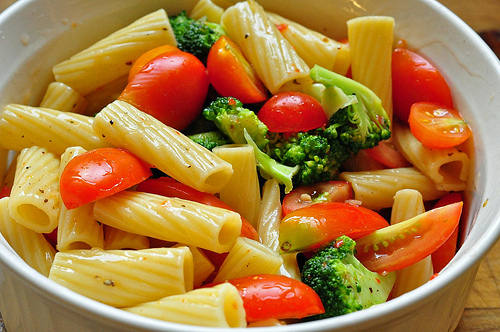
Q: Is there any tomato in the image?
A: Yes, there is a tomato.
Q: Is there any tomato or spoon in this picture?
A: Yes, there is a tomato.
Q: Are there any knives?
A: No, there are no knives.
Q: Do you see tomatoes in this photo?
A: Yes, there is a tomato.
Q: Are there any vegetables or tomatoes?
A: Yes, there is a tomato.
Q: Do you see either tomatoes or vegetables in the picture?
A: Yes, there is a tomato.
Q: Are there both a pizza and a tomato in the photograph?
A: No, there is a tomato but no pizzas.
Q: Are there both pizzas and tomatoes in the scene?
A: No, there is a tomato but no pizzas.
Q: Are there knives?
A: No, there are no knives.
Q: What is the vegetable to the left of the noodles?
A: The vegetable is a tomato.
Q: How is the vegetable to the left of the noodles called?
A: The vegetable is a tomato.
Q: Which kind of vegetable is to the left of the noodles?
A: The vegetable is a tomato.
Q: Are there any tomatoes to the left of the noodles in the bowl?
A: Yes, there is a tomato to the left of the noodles.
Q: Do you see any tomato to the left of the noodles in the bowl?
A: Yes, there is a tomato to the left of the noodles.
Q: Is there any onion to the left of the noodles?
A: No, there is a tomato to the left of the noodles.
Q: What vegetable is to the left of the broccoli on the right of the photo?
A: The vegetable is a tomato.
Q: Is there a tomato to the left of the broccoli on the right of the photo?
A: Yes, there is a tomato to the left of the broccoli.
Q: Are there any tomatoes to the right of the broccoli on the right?
A: No, the tomato is to the left of the broccoli.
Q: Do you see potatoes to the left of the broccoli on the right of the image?
A: No, there is a tomato to the left of the broccoli.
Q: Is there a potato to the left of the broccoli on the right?
A: No, there is a tomato to the left of the broccoli.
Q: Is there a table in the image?
A: Yes, there is a table.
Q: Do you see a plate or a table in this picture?
A: Yes, there is a table.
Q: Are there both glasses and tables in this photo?
A: No, there is a table but no glasses.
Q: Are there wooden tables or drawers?
A: Yes, there is a wood table.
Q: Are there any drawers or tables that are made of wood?
A: Yes, the table is made of wood.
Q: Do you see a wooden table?
A: Yes, there is a wood table.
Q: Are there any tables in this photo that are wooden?
A: Yes, there is a table that is wooden.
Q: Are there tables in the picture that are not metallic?
A: Yes, there is a wooden table.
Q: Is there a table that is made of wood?
A: Yes, there is a table that is made of wood.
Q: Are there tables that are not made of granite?
A: Yes, there is a table that is made of wood.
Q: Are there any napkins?
A: No, there are no napkins.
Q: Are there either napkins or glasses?
A: No, there are no napkins or glasses.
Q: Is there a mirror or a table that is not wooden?
A: No, there is a table but it is wooden.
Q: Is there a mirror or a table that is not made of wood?
A: No, there is a table but it is made of wood.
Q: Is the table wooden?
A: Yes, the table is wooden.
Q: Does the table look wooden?
A: Yes, the table is wooden.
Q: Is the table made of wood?
A: Yes, the table is made of wood.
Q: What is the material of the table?
A: The table is made of wood.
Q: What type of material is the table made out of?
A: The table is made of wood.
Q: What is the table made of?
A: The table is made of wood.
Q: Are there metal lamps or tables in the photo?
A: No, there is a table but it is wooden.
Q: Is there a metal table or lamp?
A: No, there is a table but it is wooden.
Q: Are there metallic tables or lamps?
A: No, there is a table but it is wooden.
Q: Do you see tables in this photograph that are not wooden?
A: No, there is a table but it is wooden.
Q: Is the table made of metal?
A: No, the table is made of wood.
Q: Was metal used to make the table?
A: No, the table is made of wood.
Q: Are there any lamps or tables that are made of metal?
A: No, there is a table but it is made of wood.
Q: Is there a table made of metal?
A: No, there is a table but it is made of wood.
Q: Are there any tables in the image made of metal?
A: No, there is a table but it is made of wood.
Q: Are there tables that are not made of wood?
A: No, there is a table but it is made of wood.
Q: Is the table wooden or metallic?
A: The table is wooden.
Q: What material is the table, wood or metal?
A: The table is made of wood.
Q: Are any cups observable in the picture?
A: No, there are no cups.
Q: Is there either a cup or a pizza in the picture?
A: No, there are no cups or pizzas.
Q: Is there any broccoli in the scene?
A: Yes, there is broccoli.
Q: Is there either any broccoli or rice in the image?
A: Yes, there is broccoli.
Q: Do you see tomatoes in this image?
A: Yes, there is a tomato.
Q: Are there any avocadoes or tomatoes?
A: Yes, there is a tomato.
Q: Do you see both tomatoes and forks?
A: No, there is a tomato but no forks.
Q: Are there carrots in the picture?
A: No, there are no carrots.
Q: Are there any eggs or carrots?
A: No, there are no carrots or eggs.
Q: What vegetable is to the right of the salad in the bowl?
A: The vegetable is a tomato.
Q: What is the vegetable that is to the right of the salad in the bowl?
A: The vegetable is a tomato.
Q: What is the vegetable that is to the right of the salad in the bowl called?
A: The vegetable is a tomato.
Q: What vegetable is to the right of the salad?
A: The vegetable is a tomato.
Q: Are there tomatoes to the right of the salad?
A: Yes, there is a tomato to the right of the salad.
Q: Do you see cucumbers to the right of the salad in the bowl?
A: No, there is a tomato to the right of the salad.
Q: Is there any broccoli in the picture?
A: Yes, there is broccoli.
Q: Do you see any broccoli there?
A: Yes, there is broccoli.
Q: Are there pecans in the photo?
A: No, there are no pecans.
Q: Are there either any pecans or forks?
A: No, there are no pecans or forks.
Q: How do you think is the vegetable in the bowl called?
A: The vegetable is broccoli.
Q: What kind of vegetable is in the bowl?
A: The vegetable is broccoli.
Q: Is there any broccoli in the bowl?
A: Yes, there is broccoli in the bowl.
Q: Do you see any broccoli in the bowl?
A: Yes, there is broccoli in the bowl.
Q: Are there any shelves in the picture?
A: No, there are no shelves.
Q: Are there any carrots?
A: No, there are no carrots.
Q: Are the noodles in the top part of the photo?
A: Yes, the noodles are in the top of the image.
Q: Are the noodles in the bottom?
A: No, the noodles are in the top of the image.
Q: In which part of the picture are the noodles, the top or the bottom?
A: The noodles are in the top of the image.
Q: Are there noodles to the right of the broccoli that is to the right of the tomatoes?
A: Yes, there are noodles to the right of the broccoli.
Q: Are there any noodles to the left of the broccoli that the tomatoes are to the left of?
A: No, the noodles are to the right of the broccoli.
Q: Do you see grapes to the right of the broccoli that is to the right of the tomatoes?
A: No, there are noodles to the right of the broccoli.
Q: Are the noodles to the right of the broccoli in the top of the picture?
A: Yes, the noodles are to the right of the broccoli.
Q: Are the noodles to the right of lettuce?
A: No, the noodles are to the right of the broccoli.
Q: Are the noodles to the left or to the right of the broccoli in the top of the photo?
A: The noodles are to the right of the broccoli.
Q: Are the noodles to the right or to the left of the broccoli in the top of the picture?
A: The noodles are to the right of the broccoli.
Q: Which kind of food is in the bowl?
A: The food is noodles.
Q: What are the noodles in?
A: The noodles are in the bowl.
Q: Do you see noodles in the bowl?
A: Yes, there are noodles in the bowl.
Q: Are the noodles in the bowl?
A: Yes, the noodles are in the bowl.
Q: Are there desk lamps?
A: No, there are no desk lamps.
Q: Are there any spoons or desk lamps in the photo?
A: No, there are no desk lamps or spoons.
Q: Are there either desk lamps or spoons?
A: No, there are no desk lamps or spoons.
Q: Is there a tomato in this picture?
A: Yes, there are tomatoes.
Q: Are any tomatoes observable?
A: Yes, there are tomatoes.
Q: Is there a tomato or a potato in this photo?
A: Yes, there are tomatoes.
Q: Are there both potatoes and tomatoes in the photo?
A: No, there are tomatoes but no potatoes.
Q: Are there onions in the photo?
A: No, there are no onions.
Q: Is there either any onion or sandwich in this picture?
A: No, there are no onions or sandwiches.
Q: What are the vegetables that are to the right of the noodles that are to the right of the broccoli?
A: The vegetables are tomatoes.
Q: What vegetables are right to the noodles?
A: The vegetables are tomatoes.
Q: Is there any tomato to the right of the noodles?
A: Yes, there are tomatoes to the right of the noodles.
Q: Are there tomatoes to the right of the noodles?
A: Yes, there are tomatoes to the right of the noodles.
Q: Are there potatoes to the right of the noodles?
A: No, there are tomatoes to the right of the noodles.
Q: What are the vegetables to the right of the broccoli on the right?
A: The vegetables are tomatoes.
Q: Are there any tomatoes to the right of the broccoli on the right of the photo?
A: Yes, there are tomatoes to the right of the broccoli.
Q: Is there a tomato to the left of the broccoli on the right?
A: No, the tomatoes are to the right of the broccoli.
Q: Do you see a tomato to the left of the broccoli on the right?
A: No, the tomatoes are to the right of the broccoli.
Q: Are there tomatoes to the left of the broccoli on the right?
A: No, the tomatoes are to the right of the broccoli.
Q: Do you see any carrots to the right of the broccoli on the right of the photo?
A: No, there are tomatoes to the right of the broccoli.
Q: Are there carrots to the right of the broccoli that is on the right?
A: No, there are tomatoes to the right of the broccoli.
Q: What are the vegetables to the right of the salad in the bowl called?
A: The vegetables are tomatoes.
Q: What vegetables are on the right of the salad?
A: The vegetables are tomatoes.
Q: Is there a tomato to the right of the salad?
A: Yes, there are tomatoes to the right of the salad.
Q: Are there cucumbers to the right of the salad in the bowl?
A: No, there are tomatoes to the right of the salad.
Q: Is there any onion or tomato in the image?
A: Yes, there are tomatoes.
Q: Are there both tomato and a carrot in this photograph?
A: No, there are tomatoes but no carrots.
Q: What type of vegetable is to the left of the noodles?
A: The vegetables are tomatoes.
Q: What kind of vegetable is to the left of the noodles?
A: The vegetables are tomatoes.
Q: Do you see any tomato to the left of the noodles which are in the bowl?
A: Yes, there are tomatoes to the left of the noodles.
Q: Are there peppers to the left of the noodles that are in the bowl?
A: No, there are tomatoes to the left of the noodles.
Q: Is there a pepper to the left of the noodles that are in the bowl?
A: No, there are tomatoes to the left of the noodles.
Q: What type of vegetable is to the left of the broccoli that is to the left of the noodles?
A: The vegetables are tomatoes.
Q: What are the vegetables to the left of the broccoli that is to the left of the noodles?
A: The vegetables are tomatoes.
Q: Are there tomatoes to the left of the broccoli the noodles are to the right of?
A: Yes, there are tomatoes to the left of the broccoli.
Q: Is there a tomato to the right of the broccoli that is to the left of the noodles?
A: No, the tomatoes are to the left of the broccoli.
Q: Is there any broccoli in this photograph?
A: Yes, there is broccoli.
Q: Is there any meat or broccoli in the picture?
A: Yes, there is broccoli.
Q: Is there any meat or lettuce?
A: No, there are no lettuce or meat.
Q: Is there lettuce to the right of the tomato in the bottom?
A: No, there is broccoli to the right of the tomato.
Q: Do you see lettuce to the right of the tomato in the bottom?
A: No, there is broccoli to the right of the tomato.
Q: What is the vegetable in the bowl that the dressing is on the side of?
A: The vegetable is broccoli.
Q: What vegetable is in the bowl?
A: The vegetable is broccoli.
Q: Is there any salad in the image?
A: Yes, there is salad.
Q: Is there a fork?
A: No, there are no forks.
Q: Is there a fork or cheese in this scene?
A: No, there are no forks or cheese.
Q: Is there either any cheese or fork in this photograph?
A: No, there are no forks or cheese.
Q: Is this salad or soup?
A: This is salad.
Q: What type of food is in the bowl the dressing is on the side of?
A: The food is salad.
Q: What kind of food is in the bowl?
A: The food is salad.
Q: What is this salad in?
A: The salad is in the bowl.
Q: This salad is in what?
A: The salad is in the bowl.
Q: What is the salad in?
A: The salad is in the bowl.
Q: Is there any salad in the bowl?
A: Yes, there is salad in the bowl.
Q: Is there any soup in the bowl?
A: No, there is salad in the bowl.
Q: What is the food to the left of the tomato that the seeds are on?
A: The food is salad.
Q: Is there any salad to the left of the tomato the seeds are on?
A: Yes, there is salad to the left of the tomato.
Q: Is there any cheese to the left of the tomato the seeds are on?
A: No, there is salad to the left of the tomato.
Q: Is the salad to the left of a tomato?
A: Yes, the salad is to the left of a tomato.